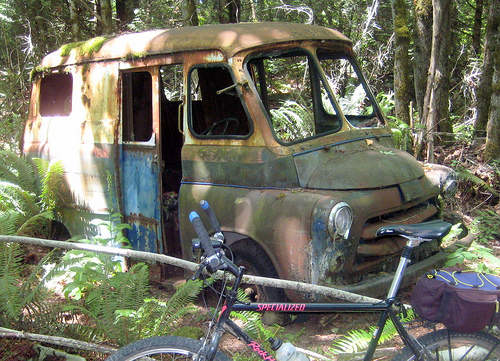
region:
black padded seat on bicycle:
[353, 220, 467, 258]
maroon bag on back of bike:
[411, 258, 497, 325]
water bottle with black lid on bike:
[262, 328, 292, 357]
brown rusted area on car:
[364, 194, 414, 206]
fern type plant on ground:
[106, 261, 201, 328]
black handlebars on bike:
[183, 194, 276, 296]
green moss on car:
[68, 40, 125, 64]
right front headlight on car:
[311, 178, 366, 237]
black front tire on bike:
[110, 300, 189, 358]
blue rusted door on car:
[110, 134, 160, 234]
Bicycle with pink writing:
[119, 201, 498, 358]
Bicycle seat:
[368, 218, 453, 248]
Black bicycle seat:
[367, 213, 459, 255]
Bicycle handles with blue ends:
[167, 196, 248, 278]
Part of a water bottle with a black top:
[260, 331, 313, 359]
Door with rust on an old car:
[112, 56, 192, 277]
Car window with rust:
[175, 51, 256, 147]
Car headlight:
[325, 201, 354, 248]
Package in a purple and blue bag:
[405, 245, 499, 335]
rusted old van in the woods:
[18, 11, 471, 300]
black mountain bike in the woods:
[96, 185, 499, 359]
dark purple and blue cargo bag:
[408, 258, 499, 335]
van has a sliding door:
[118, 62, 184, 281]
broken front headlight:
[324, 202, 359, 242]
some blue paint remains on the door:
[114, 138, 168, 275]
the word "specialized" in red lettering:
[251, 300, 306, 313]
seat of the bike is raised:
[371, 217, 454, 302]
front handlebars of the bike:
[186, 189, 236, 279]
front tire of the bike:
[96, 329, 244, 359]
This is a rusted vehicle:
[15, 16, 467, 307]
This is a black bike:
[54, 185, 498, 358]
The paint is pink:
[187, 267, 317, 359]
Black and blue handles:
[159, 190, 260, 295]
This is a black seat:
[352, 205, 474, 294]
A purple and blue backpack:
[398, 259, 498, 346]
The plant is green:
[1, 133, 176, 358]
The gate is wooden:
[3, 227, 441, 358]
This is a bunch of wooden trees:
[10, 3, 499, 220]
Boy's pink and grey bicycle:
[83, 194, 498, 354]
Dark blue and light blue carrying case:
[411, 262, 497, 339]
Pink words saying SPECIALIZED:
[252, 300, 310, 315]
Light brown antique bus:
[14, 15, 469, 316]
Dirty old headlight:
[322, 195, 358, 245]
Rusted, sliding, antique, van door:
[103, 55, 198, 285]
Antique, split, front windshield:
[238, 40, 396, 150]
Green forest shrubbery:
[0, 146, 249, 345]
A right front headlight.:
[330, 200, 355, 242]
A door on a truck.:
[118, 59, 163, 274]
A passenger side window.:
[236, 46, 343, 145]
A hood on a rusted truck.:
[292, 136, 458, 199]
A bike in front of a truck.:
[104, 199, 495, 359]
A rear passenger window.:
[35, 70, 76, 118]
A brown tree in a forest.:
[402, 0, 460, 162]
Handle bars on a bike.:
[182, 197, 259, 313]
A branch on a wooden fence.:
[1, 322, 127, 357]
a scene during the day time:
[4, 5, 499, 357]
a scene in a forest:
[6, 6, 497, 354]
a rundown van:
[16, 15, 473, 327]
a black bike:
[93, 192, 488, 359]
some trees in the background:
[5, 1, 496, 183]